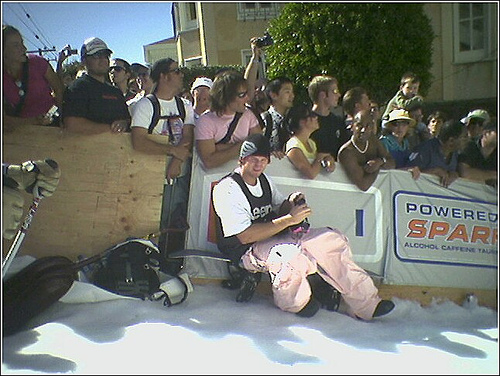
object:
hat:
[236, 132, 274, 163]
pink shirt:
[194, 107, 260, 152]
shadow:
[2, 321, 78, 374]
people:
[129, 57, 195, 185]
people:
[193, 69, 264, 169]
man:
[194, 68, 264, 170]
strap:
[214, 108, 243, 145]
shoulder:
[237, 106, 258, 120]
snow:
[2, 285, 497, 375]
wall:
[1, 116, 498, 309]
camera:
[40, 105, 66, 127]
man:
[336, 107, 397, 193]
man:
[61, 37, 131, 134]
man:
[250, 74, 301, 161]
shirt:
[210, 172, 296, 240]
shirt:
[130, 87, 199, 152]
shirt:
[63, 67, 129, 132]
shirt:
[3, 53, 58, 127]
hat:
[76, 37, 114, 58]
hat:
[189, 75, 212, 95]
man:
[209, 132, 396, 320]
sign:
[391, 188, 500, 270]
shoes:
[351, 297, 395, 320]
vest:
[207, 172, 283, 253]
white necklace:
[349, 136, 372, 154]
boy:
[381, 77, 423, 130]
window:
[452, 3, 499, 61]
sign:
[195, 171, 384, 265]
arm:
[241, 49, 260, 99]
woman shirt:
[1, 55, 56, 122]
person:
[279, 100, 336, 179]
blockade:
[1, 127, 498, 307]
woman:
[380, 108, 416, 170]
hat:
[381, 108, 419, 130]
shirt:
[282, 134, 321, 167]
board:
[4, 122, 162, 269]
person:
[4, 22, 66, 120]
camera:
[250, 35, 276, 46]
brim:
[87, 47, 114, 56]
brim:
[188, 84, 216, 92]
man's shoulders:
[378, 134, 395, 146]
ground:
[0, 302, 500, 376]